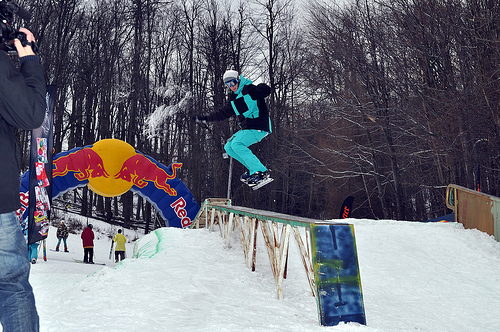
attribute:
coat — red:
[81, 226, 96, 246]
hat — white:
[211, 57, 244, 85]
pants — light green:
[227, 125, 273, 195]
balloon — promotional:
[45, 147, 205, 207]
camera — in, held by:
[6, 14, 58, 58]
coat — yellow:
[107, 234, 127, 252]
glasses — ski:
[218, 78, 238, 90]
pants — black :
[81, 245, 98, 262]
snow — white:
[17, 217, 497, 329]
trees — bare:
[1, 0, 498, 228]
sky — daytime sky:
[1, 0, 474, 146]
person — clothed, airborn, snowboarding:
[194, 67, 277, 189]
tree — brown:
[132, 22, 154, 157]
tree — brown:
[145, 22, 173, 150]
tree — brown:
[175, 22, 187, 173]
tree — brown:
[179, 33, 201, 187]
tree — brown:
[194, 27, 220, 194]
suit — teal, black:
[201, 64, 281, 194]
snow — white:
[23, 202, 498, 329]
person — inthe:
[81, 223, 96, 263]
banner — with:
[36, 147, 203, 232]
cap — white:
[218, 64, 243, 86]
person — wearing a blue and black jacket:
[191, 68, 273, 184]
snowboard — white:
[240, 170, 275, 190]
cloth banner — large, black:
[25, 89, 62, 246]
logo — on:
[49, 153, 188, 223]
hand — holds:
[4, 26, 39, 54]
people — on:
[56, 211, 67, 255]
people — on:
[204, 59, 268, 183]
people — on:
[79, 211, 95, 262]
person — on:
[220, 65, 270, 189]